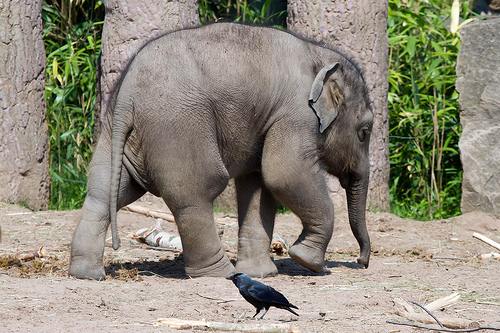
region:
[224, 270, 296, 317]
the bird is blue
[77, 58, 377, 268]
the elephant is a baby calf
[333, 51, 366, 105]
there is hair is on the head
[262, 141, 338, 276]
the foot is not touching the ground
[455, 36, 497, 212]
the stone is thick concrete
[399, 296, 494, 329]
the twig iss on the road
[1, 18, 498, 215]
there are four colums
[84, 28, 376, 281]
the elephant has four legs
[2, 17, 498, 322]
the photo was taken outside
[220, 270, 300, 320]
the bird is small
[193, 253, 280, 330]
A bird is visible.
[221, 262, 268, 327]
A bird is visible.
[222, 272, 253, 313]
A bird is visible.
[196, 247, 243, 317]
A bird is visible.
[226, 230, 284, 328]
A bird is visible.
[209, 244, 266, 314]
A bird is visible.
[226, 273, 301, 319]
black bird on ground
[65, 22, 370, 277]
baby elephant behind black bird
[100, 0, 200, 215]
large tree trunk behind elephant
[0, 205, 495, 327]
dirty ground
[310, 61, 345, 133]
ear on baby elephant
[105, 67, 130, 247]
tail of baby elephant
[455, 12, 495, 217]
large gray rock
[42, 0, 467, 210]
bright green foliage behind trunks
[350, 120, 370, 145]
eye of baby elephant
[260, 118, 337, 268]
right front leg of baby elephant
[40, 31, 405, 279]
A baby elephant.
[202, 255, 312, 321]
A black bird.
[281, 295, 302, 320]
The tail of a bird.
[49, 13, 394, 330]
A bird is next to an elephant.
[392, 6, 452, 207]
Green leaves on the plant.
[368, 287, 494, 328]
A stick on the ground.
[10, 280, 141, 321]
Dirt on the ground.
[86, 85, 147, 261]
The elephant has a tail.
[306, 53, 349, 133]
The elephant has an ear.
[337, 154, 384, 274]
The elephant has a trunk.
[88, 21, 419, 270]
a baby elephant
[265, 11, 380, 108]
elephant has hair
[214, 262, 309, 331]
bird is on the ground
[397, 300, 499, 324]
a twig on the ground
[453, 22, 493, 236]
large rock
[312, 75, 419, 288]
elephant's trunk is on the ground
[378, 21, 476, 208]
the leaves are green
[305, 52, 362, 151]
the baby elephant's ear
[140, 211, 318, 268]
tree branches on the ground